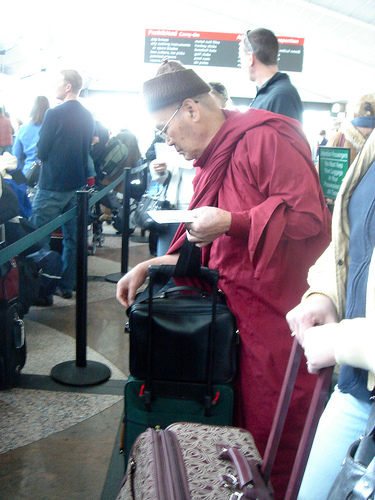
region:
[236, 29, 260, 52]
sunglasses on man's head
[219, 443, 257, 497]
handle on the suitcase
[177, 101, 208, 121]
the man's left ear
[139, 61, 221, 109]
brown hat on the man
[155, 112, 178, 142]
glasses on the man's face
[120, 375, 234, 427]
green suitcase on the ground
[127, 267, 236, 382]
a black suitcase on ground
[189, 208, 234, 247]
the old man's left hand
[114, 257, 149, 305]
the man's right hand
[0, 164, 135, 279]
black rope attached to poles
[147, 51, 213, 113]
brown hat on the man's head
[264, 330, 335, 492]
a purple suitcase handle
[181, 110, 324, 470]
a traditional red dress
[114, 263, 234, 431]
two dark suitcases stacked on each other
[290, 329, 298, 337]
a ring on her finger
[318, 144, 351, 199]
a green instruction sign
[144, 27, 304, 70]
red and black informational sign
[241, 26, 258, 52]
sunglasses on the man's head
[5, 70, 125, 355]
a line of people at the airport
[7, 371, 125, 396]
a dark stripe in the tile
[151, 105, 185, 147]
part of a man's eyeglasses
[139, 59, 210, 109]
a brown cap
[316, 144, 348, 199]
a green and white sign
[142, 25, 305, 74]
a long black, white and red sign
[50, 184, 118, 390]
a tall black pole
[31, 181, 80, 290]
part of a man's blue jean pants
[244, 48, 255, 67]
the ear of a man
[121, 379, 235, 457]
part of a green suitcase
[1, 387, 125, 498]
part of a tile floor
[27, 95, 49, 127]
a person's long hair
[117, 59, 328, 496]
a man dressed in a red robe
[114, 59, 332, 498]
man holding a piece of paper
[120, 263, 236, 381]
a black travel bag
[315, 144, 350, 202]
a green sign with white lettering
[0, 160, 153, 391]
a rope railing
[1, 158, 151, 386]
three metal poles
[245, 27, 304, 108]
a man with sunglasses on his head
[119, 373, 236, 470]
a green suitcase with a red accent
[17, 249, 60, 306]
a black backpack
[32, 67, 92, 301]
a man wearing blue jeans and a black shirt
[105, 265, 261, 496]
different luggages on the scene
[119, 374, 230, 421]
this bag is green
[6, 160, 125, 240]
a long green belt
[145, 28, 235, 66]
an illegible sign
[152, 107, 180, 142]
he is wearing eyeglasses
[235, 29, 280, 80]
the head of the man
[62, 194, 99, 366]
a vertical metal bar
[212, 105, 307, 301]
he is in red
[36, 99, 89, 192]
thi is blue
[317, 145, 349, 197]
this sign is green